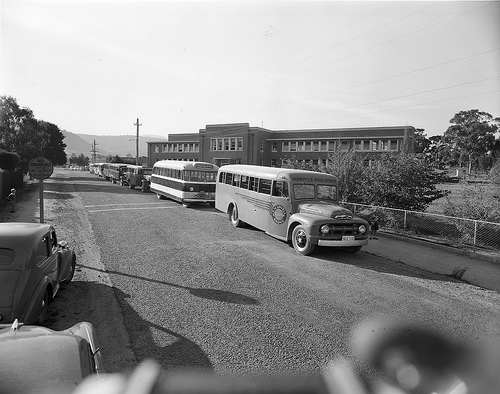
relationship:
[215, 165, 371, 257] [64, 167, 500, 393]
bus parked on street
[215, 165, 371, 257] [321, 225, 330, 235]
bus has headlight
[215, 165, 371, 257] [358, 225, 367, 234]
bus has headlight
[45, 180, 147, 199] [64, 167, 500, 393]
shadow cast onto street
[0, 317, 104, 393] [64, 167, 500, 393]
car parked on street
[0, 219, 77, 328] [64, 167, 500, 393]
car parked on street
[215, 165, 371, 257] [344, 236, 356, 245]
bus has plate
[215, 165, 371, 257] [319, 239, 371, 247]
bus has bumper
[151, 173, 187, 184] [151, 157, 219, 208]
rail on side of bus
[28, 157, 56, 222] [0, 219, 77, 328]
sign in front of car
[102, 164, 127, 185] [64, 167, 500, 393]
bus parked on street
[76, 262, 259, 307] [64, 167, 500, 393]
shadow cast onto street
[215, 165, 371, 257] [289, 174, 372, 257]
bus has front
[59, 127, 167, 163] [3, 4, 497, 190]
mountains way in back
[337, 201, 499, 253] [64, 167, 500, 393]
fence on side of street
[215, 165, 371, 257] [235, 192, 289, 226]
bus has logo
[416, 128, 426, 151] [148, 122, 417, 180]
tree near building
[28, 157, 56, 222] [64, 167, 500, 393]
sign beside street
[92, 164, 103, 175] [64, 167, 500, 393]
bus parked by street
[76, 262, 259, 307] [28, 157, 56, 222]
shadow cast by sign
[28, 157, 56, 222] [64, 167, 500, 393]
sign on side of street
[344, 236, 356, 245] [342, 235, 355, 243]
plate for plate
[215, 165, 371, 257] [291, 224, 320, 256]
bus has wheel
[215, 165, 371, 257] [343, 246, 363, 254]
bus has wheel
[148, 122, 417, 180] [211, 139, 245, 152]
building has windows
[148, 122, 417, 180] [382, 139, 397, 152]
building has windows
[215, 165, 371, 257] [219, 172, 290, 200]
bus has windows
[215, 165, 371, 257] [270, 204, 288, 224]
bus has circle